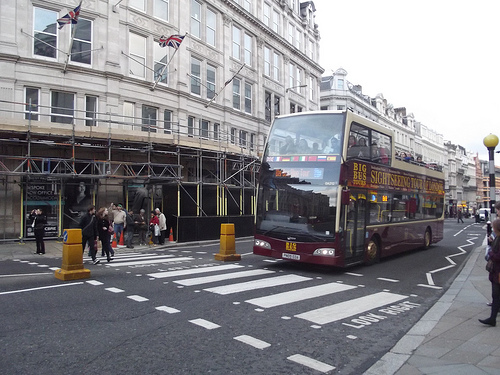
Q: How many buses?
A: One.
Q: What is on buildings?
A: Flags.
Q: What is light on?
A: Pole.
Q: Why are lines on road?
A: Crosswalk.